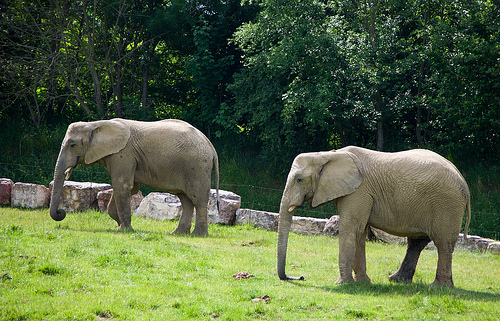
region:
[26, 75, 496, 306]
two elephants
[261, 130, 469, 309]
an elephant with the trunk touching the grassy ground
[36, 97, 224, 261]
an elephant with a partially curved trunk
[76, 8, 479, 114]
trees with lots of leaves in the background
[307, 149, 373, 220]
an elephant with floppy ear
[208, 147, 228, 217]
a tail of an elephant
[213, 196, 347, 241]
stones lined next to each other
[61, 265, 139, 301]
a patch of grass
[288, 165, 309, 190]
a left eye of the elephant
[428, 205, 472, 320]
one of the four legs of an elephant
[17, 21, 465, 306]
a scene outside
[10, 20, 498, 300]
a scene during the day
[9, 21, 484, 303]
a scene at a field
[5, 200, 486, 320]
some green grass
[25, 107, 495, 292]
two elephants walking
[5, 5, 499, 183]
trees line the background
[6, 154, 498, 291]
a wall made of gray stone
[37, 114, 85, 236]
trunks on an elephant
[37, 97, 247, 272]
an elephant in front of another one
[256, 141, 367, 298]
an elephant's head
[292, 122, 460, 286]
This elephant is a light grey in color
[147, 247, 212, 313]
The grass is very, very green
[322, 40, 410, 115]
The trees are very, very green in the distance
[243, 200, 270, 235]
There is a grey rock that is in the distance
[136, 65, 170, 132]
There is a grey trunk that is on the tree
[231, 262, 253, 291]
There is a clump of brown on the ground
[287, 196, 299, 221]
There is a tusk on the elephant that is bright white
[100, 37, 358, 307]
This is in the state of Ohio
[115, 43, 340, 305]
This is in the city of Dayton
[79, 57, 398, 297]
This is taken by the photographer Jackson Mingus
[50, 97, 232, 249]
an elephant in the field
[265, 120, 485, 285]
an elephant in the field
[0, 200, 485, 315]
A grassy field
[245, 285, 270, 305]
some elephant excrement on the field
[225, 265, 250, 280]
some elephant excrement on the field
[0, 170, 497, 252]
A line of large rocks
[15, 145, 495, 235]
A small wired fence behind the rocks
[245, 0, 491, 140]
A large full tree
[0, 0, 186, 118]
A leafless tree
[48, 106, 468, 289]
A pair of elephants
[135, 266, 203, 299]
ground covered in green grass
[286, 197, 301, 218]
small white elephant tusk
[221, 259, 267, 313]
animal droppings on ground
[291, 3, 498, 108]
trees covered in green leaves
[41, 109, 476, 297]
two elephants walking in field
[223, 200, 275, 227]
large grey rocks on edge on field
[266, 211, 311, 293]
grey elephant trunk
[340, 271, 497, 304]
shadow of elephant on ground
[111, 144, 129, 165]
black spot on side of elephant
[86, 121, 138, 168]
large grey elephant ear